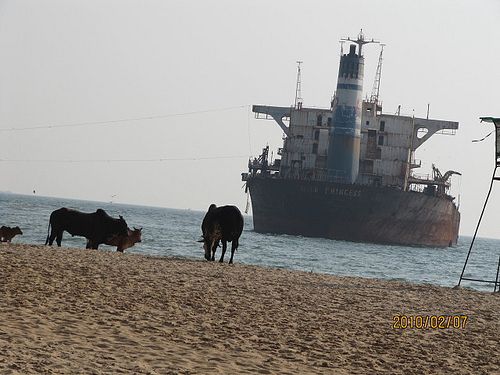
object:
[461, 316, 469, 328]
number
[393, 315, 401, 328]
number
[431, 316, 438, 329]
number